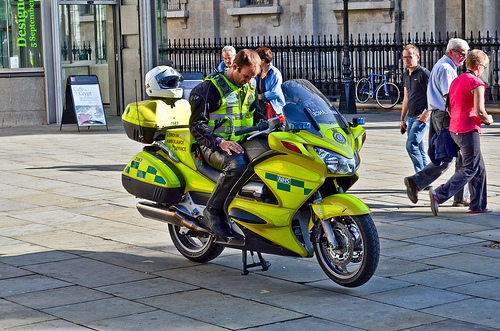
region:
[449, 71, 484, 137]
woman's shirt is red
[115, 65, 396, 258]
the motorcycle is yellow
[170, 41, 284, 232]
man sitting on motorcycle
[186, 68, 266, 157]
man wearing a yellow vest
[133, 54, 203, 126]
the helmet is white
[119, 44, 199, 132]
helmet sitting on back of motorcycle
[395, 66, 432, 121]
man's shirt is black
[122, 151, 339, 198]
green rectangles on motorcycle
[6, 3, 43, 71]
green letters on window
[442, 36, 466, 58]
man is wearing sunglasses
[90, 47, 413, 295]
a yellow motorbike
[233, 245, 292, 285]
the bike is on a stand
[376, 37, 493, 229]
a group of pedestrians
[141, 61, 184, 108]
a white helmet on the back of the bike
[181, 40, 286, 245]
a man is sitting on the motor bike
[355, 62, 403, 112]
a blue bicycle leaning on a gate.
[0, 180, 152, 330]
concrete blocks complete the walkway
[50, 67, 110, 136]
a sign sits in front of a store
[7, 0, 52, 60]
a decal on the front of the store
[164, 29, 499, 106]
a black gate lining the back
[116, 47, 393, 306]
A man on a motorcycle.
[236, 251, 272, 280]
A kickstand for the motorcycle.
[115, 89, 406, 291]
A neon yellow motorcycle.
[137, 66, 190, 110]
A white helmet.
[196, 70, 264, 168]
A yellow reflector vest.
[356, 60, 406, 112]
A blue framed bicycle.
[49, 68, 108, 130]
A sign in front of a shop.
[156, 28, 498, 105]
A black metal fence.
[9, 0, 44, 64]
A green decal on a window.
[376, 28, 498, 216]
People walking around.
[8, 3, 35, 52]
the word design in green writing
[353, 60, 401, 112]
unattended blue bicycle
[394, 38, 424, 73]
man wearing glasses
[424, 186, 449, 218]
white shoe with red stripes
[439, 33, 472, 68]
gray haired man wearing glasses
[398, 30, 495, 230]
man and woman walking together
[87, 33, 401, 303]
man on yellow motorcycle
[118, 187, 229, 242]
chrome motorcycle muffler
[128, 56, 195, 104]
white motorcycle helmet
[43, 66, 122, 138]
sandwich board with advertising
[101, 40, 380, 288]
man on motorcycle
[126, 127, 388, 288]
yellow motorcycle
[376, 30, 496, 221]
three people walking on street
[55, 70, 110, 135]
sign standing on sidewalk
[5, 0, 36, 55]
green lettering on storefront window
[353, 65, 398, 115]
bicycle with blue frame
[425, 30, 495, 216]
man and woman walking down the street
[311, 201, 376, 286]
front wheel and tire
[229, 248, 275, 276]
kickstand underneath a motorcycle